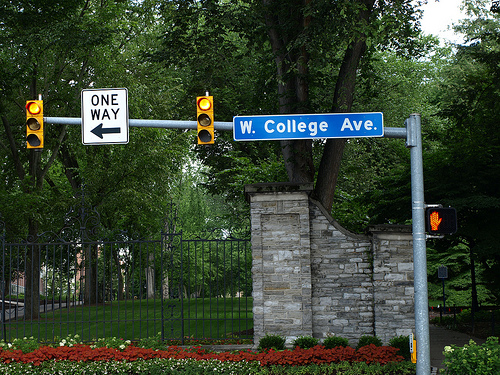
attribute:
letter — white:
[351, 117, 365, 132]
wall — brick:
[248, 195, 423, 349]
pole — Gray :
[380, 121, 415, 138]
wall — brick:
[196, 183, 433, 370]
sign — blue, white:
[230, 110, 385, 143]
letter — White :
[290, 118, 297, 135]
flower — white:
[444, 345, 454, 355]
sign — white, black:
[81, 85, 127, 145]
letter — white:
[238, 120, 251, 134]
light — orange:
[191, 93, 220, 150]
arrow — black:
[89, 122, 121, 134]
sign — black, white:
[77, 84, 132, 148]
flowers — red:
[4, 337, 416, 365]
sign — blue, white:
[81, 89, 132, 146]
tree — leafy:
[165, 1, 430, 218]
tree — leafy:
[42, 0, 188, 302]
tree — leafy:
[1, 0, 112, 319]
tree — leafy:
[145, 169, 201, 296]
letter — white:
[293, 123, 305, 134]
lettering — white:
[237, 119, 379, 136]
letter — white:
[309, 120, 320, 137]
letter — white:
[294, 117, 309, 135]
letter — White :
[332, 106, 358, 140]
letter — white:
[276, 120, 284, 132]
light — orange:
[194, 98, 214, 110]